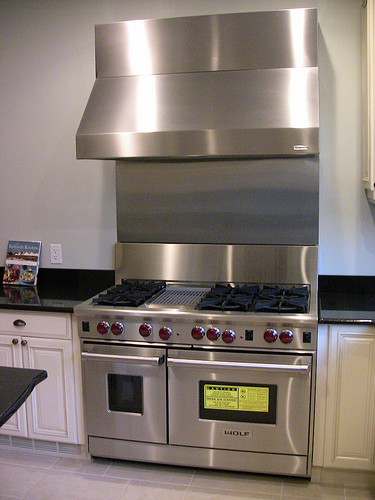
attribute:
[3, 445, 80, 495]
floor — Part  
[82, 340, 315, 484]
oven — silver, shiny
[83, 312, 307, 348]
dials — red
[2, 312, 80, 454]
cabinents — white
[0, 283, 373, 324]
counter — black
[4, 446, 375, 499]
floor — Part , tiled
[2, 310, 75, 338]
drawer — white